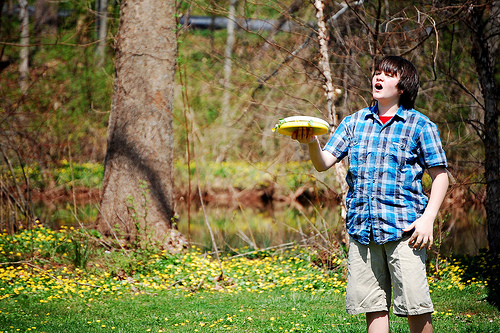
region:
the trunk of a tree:
[85, 6, 199, 256]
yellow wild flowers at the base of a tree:
[94, 247, 313, 297]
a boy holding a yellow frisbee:
[272, 49, 455, 328]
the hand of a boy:
[402, 208, 439, 256]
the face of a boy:
[370, 68, 392, 99]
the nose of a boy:
[372, 71, 387, 83]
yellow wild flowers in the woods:
[4, 218, 71, 251]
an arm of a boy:
[400, 135, 455, 255]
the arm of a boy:
[300, 111, 355, 179]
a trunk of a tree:
[307, 5, 346, 108]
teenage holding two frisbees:
[272, 56, 452, 331]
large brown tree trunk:
[97, 4, 183, 246]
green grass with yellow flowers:
[7, 245, 477, 330]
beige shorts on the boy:
[345, 239, 435, 316]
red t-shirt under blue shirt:
[377, 115, 390, 125]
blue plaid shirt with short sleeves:
[327, 104, 446, 240]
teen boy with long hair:
[295, 58, 447, 331]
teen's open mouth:
[375, 82, 385, 89]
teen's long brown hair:
[372, 56, 417, 108]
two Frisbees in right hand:
[279, 117, 328, 144]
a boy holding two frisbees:
[268, 39, 462, 317]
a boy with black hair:
[366, 47, 425, 122]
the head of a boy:
[356, 46, 418, 116]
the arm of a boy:
[403, 123, 453, 258]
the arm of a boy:
[281, 93, 351, 194]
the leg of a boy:
[393, 254, 439, 331]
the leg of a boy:
[342, 240, 394, 331]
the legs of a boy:
[344, 239, 446, 331]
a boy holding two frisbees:
[269, 48, 479, 331]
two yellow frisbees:
[270, 104, 340, 150]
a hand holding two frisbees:
[265, 104, 331, 153]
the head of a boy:
[356, 55, 419, 112]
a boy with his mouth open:
[356, 50, 428, 122]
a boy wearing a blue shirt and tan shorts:
[266, 54, 470, 329]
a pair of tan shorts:
[343, 235, 438, 321]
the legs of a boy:
[346, 247, 441, 332]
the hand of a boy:
[403, 213, 438, 256]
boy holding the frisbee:
[254, 39, 427, 311]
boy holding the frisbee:
[271, 44, 435, 244]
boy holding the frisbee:
[250, 31, 417, 221]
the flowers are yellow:
[14, 251, 281, 315]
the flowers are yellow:
[22, 248, 284, 313]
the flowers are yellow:
[15, 251, 278, 321]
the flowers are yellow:
[4, 220, 282, 310]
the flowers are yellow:
[10, 240, 264, 305]